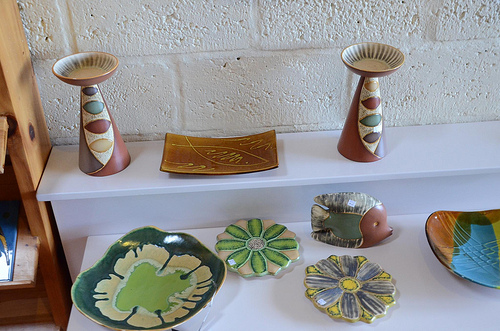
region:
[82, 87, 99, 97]
oval design on statue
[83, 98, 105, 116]
oval design on statue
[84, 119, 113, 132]
oval design on statue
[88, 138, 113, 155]
oval design on statue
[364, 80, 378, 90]
oval design on statue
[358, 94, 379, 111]
oval design on statue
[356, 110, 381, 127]
oval design on statue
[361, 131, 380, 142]
oval design on statue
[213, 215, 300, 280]
glass plate with flower design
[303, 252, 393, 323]
glass plate with flower design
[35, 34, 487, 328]
items on display on a white shelf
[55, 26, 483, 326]
pottery items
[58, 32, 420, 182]
two candle holders with oval design on front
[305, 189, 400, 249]
fish made with pottery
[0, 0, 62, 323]
wooden book shelf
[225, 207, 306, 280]
pottery with a green flower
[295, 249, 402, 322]
pottery with a blue and yellow flower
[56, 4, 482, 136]
concrete wall painted white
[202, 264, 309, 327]
shadows on the white shelf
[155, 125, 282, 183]
small piece of brown pottery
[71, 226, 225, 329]
a green craft bowl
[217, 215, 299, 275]
a green and white craft plate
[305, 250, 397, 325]
a yellow and blue craft plate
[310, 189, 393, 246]
a craft made fish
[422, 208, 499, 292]
a colorful craft bowl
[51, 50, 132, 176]
a colorful craft candlestick holder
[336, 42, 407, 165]
a colorful craft candlestick holder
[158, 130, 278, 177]
a brown craft dish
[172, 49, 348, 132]
a white painted brick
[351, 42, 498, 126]
a white painted brick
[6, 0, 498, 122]
a wall being shown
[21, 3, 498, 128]
the wall is white in color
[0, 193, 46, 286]
books around the area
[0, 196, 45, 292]
the amount of books are two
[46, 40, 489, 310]
colorful and pretty creations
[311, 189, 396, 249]
a colorful fish object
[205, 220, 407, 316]
very colorful flower objects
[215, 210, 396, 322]
the amount of flower objects are two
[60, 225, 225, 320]
a bowl looking object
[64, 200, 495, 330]
two bowl looking objects that are designed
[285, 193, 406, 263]
A ceramic fish on the table.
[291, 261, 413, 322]
Flower dish on the table.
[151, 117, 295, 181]
A dish on the step.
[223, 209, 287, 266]
A green flower on the dish.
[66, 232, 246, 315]
A green ashtray with design.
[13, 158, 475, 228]
The steps is white.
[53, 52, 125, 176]
Tall dish on the step.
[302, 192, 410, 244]
A fish on the step.